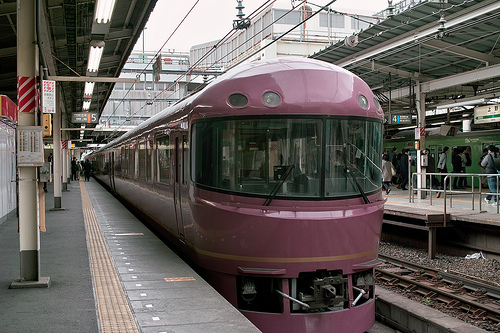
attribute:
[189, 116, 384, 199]
window —  large,  rounded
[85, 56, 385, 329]
train —  green,  for commuter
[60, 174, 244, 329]
concrete —  painted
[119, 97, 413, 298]
commuter — purple, long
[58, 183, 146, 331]
yellow lines —  yellow,   for safety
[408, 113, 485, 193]
train — green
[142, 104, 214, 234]
train door — closed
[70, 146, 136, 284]
platform — covered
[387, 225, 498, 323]
tracks next — empty